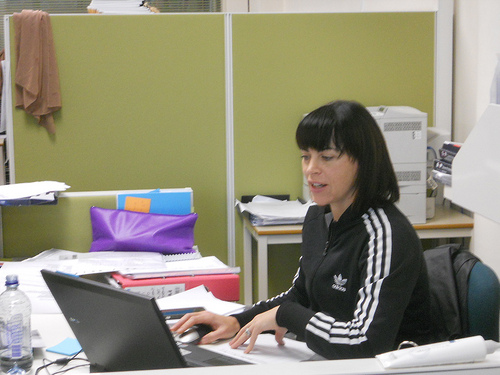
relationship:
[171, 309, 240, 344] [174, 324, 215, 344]
hand on mouse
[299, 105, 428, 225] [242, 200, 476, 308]
printer on table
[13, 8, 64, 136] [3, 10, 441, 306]
sweater hanging from wall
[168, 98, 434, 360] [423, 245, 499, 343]
woman sitting in chair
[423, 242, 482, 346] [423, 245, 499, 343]
coat hanging on chair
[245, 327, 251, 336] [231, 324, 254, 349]
ring around finger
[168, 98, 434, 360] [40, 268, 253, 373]
woman looking at laptop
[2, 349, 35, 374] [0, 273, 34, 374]
water in bottle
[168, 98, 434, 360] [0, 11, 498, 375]
woman in cubicle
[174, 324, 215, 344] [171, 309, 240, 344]
mouse under hand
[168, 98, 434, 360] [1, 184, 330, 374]
woman sitting at desk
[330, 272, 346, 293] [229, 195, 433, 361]
logo on front of jacket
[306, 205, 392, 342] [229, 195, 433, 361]
stripes on jacket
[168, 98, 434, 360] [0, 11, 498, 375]
woman working in cubicle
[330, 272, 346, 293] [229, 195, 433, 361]
logo on jacket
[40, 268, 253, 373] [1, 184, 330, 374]
laptop on desk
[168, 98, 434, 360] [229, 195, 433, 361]
woman wearing jacket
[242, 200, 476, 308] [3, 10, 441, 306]
table next to wall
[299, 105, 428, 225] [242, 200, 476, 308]
printer on top of table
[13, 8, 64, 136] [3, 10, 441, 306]
sweater hanging over wall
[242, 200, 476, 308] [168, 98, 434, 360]
table behind woman